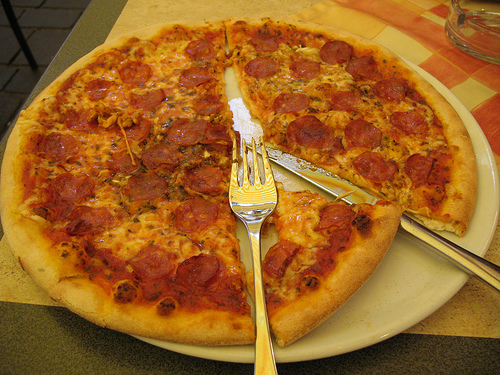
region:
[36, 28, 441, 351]
round pizza on plate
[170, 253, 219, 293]
red pepperoni on pizza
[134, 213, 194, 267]
melted cheese on pizza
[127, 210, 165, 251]
oregano on round pizza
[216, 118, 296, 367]
silver fork on pizza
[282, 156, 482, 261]
silver knife on pizza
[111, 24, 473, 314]
white plate on counter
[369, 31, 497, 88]
red and white table cloth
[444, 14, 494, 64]
clear glass on right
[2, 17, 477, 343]
large pizza with pepperoni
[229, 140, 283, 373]
a piece of silverware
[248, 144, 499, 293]
a piece of silverware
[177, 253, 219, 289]
a slice of pepperoni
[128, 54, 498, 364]
a white platter for pizza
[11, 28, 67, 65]
dark tile on the floor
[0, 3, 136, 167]
part of the gray countertop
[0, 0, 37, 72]
one leg from a chair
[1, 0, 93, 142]
the dark tiled floor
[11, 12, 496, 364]
pizza on white plate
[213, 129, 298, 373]
metal fork on pizza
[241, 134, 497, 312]
butter knife on plate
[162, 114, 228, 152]
pepperoni on pizza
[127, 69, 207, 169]
seasoning on top of pizza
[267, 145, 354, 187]
grease on edge of butter knife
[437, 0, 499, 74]
edge of drinking glass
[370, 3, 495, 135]
orange pattern on top of table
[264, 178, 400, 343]
A partially eaten pizza piece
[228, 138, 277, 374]
A fork to eat pizza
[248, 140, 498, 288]
A knife to cut pizza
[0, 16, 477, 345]
Pizza on a white ceramic plate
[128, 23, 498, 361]
White ceramic plate holding pizza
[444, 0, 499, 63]
A glass of water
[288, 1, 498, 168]
Part of a mat on the table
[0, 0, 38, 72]
Leg of a dining chair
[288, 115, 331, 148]
One of the tomato slices on the pizza topping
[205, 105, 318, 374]
a silver fork on a pizza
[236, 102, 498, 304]
a knife on a plate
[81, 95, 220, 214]
a bunch of pepperoni on pizza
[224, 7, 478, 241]
a big slice of pizza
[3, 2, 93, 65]
tiles in the floor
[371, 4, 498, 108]
red and white table cloth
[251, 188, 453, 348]
half eaten piece of pizza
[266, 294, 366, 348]
part of a pizza crust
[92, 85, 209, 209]
cheese and pepperoni pizza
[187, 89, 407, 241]
part of a fork and knife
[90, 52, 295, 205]
the pizza is baked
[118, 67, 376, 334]
this is a pepperoni pizza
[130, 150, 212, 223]
the pepperonis are red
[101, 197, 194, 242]
the cheese is melted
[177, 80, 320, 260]
this is a fork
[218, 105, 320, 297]
the fork is silver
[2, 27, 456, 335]
a pepperoni pizza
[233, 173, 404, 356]
a eaten slice of pizza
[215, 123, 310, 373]
a silver fork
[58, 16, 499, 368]
a white plate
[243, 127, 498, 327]
a silver knife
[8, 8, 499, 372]
a scene at a restaurant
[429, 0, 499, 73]
a glass object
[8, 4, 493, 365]
a gray table